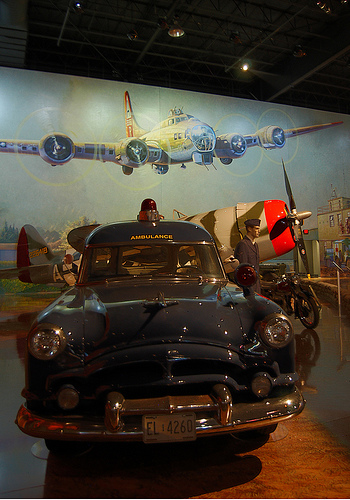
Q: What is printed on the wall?
A: A vintage airplane.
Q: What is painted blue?
A: An old fashioned ambulance.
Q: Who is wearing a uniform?
A: A male statue.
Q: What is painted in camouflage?
A: A vintage airplane.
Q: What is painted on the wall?
A: Tree and grass.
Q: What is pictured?
A: An old ambulance.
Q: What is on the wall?
A: A painting of an airplane.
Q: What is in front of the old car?
A: Headlights.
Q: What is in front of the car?
A: It's bumper and license.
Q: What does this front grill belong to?
A: Antique car.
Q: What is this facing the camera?
A: A car.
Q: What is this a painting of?
A: A plane.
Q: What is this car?
A: An old style ambulance.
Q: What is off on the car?
A: The headlights.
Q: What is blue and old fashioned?
A: Ambulance.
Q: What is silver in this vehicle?
A: Old fashioned bumper.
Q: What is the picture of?
A: Large propeller plane.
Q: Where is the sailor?
A: In front of propeller plane.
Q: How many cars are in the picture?
A: One.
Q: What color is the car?
A: Black.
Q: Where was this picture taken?
A: Inside a museum.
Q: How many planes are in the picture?
A: Two.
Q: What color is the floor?
A: Brown.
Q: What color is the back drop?
A: Blue.